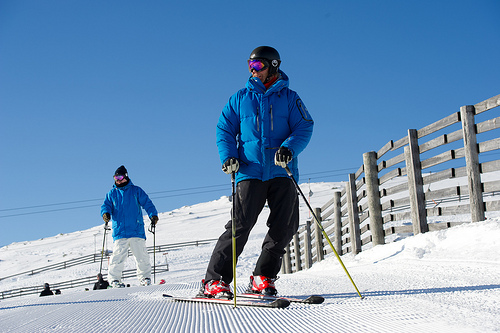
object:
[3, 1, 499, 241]
sky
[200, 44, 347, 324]
person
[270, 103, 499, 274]
fence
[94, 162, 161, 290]
person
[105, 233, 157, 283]
pants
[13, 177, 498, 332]
snow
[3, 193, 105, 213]
power lines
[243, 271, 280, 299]
ski boots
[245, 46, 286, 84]
helmet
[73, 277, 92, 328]
tracks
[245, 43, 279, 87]
head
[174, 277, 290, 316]
skis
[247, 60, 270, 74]
goggles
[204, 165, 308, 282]
pants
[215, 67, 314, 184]
coat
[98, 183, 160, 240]
jacket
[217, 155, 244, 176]
gloves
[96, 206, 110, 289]
left ski pole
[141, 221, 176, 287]
right ski pole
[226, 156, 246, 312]
left ski pole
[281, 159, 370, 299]
right ski pole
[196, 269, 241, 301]
left ski boot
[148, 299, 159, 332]
lines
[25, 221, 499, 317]
ground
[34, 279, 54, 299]
people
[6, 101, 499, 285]
background